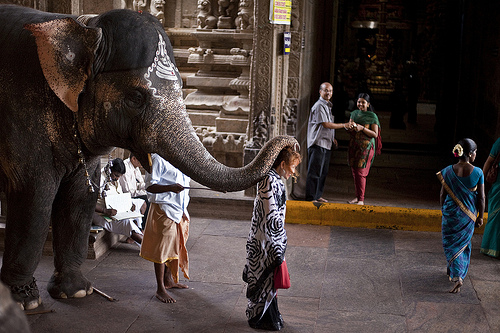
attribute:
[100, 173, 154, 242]
dress — white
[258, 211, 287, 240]
flower — black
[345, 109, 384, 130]
scarf — green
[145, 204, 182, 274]
skirt — peach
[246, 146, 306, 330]
person — standing outside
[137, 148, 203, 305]
person — standing outside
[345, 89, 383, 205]
person — standing outside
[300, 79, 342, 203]
person — standing outside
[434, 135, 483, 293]
person — standing outside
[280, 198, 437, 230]
line — yellow